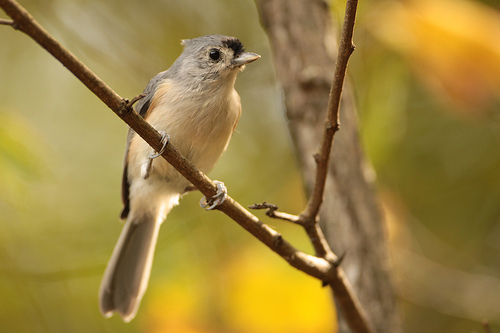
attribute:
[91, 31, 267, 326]
bird — white color, white, gray, grey, common, on lookout, sitting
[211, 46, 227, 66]
eye — black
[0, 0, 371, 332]
tree branch — brown color, brown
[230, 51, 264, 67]
beak — small, grey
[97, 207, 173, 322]
tail — grey, long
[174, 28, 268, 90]
head — black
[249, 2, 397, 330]
trunk — brown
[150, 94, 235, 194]
breast — cream colored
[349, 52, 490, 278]
leaves — green